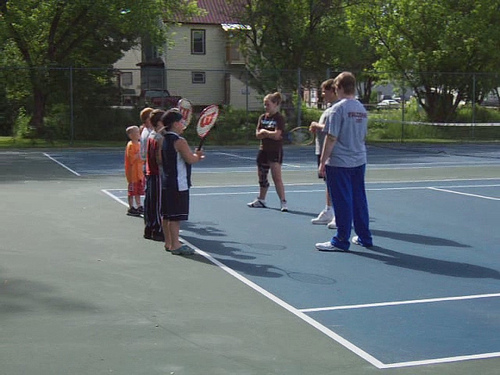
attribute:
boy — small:
[125, 126, 147, 218]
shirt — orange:
[123, 142, 147, 186]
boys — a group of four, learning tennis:
[123, 108, 204, 258]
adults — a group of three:
[244, 68, 373, 253]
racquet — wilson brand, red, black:
[195, 103, 220, 155]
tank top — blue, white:
[161, 132, 193, 192]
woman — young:
[248, 90, 288, 214]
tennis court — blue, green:
[0, 147, 498, 373]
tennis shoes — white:
[248, 197, 289, 211]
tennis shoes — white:
[310, 210, 337, 229]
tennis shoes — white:
[315, 234, 370, 253]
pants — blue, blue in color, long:
[322, 161, 375, 249]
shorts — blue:
[316, 153, 329, 183]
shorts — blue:
[157, 175, 191, 223]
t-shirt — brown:
[259, 112, 288, 148]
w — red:
[198, 110, 217, 128]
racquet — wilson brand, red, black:
[176, 97, 196, 134]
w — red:
[177, 105, 190, 123]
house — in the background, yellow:
[96, 2, 292, 113]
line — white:
[43, 153, 82, 179]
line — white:
[100, 189, 129, 206]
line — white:
[180, 238, 386, 370]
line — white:
[305, 284, 499, 316]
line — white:
[382, 343, 500, 371]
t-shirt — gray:
[323, 99, 370, 168]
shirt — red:
[145, 130, 166, 181]